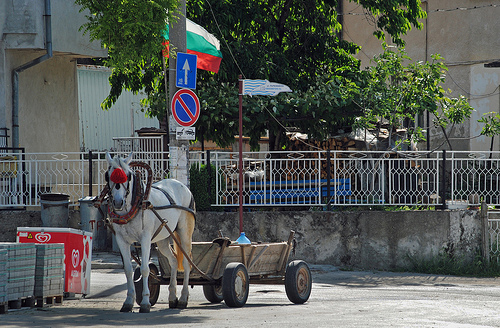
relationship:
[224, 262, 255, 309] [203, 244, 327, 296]
wheels on wagon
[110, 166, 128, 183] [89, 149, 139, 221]
tassle in front of head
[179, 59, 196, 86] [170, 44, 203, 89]
arrow on blue sign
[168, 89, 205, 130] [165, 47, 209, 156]
circle line on sign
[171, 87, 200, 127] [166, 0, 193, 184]
sign on pole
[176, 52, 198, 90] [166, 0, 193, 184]
blue sign on pole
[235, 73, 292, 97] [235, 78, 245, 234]
flag on pole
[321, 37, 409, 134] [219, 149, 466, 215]
trees behind fence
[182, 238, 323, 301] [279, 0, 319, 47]
wagon on wheels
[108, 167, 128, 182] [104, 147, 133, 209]
flower on head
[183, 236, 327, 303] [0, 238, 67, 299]
palates stacked with bricks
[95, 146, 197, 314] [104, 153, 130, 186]
horse with pom pom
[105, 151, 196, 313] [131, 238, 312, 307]
horse hauling wagon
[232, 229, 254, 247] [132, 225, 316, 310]
blue bottle in wooden wagon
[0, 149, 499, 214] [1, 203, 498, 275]
fence on top of wall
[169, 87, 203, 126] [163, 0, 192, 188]
sign on pole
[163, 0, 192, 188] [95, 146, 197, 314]
pole behind horse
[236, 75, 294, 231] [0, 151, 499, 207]
street sign next to fence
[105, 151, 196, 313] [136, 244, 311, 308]
horse with trailer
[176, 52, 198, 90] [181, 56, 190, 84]
blue sign with arrow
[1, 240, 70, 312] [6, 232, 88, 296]
pallets of materials